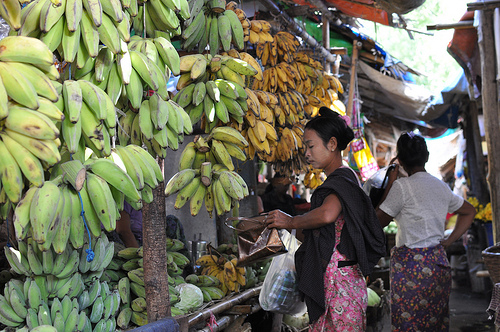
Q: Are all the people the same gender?
A: Yes, all the people are female.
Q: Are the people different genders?
A: No, all the people are female.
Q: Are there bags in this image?
A: Yes, there is a bag.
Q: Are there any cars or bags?
A: Yes, there is a bag.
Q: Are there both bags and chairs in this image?
A: No, there is a bag but no chairs.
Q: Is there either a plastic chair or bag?
A: Yes, there is a plastic bag.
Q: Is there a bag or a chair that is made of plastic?
A: Yes, the bag is made of plastic.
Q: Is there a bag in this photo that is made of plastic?
A: Yes, there is a bag that is made of plastic.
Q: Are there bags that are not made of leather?
A: Yes, there is a bag that is made of plastic.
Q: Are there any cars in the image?
A: No, there are no cars.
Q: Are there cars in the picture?
A: No, there are no cars.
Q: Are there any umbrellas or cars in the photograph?
A: No, there are no cars or umbrellas.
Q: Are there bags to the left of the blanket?
A: Yes, there is a bag to the left of the blanket.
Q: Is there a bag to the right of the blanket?
A: No, the bag is to the left of the blanket.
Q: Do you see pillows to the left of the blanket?
A: No, there is a bag to the left of the blanket.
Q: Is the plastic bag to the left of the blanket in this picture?
A: Yes, the bag is to the left of the blanket.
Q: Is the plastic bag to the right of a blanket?
A: No, the bag is to the left of a blanket.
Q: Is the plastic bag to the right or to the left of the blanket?
A: The bag is to the left of the blanket.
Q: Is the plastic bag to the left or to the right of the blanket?
A: The bag is to the left of the blanket.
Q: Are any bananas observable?
A: Yes, there are bananas.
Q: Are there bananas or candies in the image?
A: Yes, there are bananas.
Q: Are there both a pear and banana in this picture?
A: No, there are bananas but no pears.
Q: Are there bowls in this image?
A: No, there are no bowls.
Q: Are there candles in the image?
A: No, there are no candles.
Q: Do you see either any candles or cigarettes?
A: No, there are no candles or cigarettes.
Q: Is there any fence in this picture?
A: No, there are no fences.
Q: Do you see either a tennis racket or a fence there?
A: No, there are no fences or rackets.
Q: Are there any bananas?
A: Yes, there are bananas.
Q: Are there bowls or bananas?
A: Yes, there are bananas.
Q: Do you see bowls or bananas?
A: Yes, there are bananas.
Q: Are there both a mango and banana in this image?
A: No, there are bananas but no mangoes.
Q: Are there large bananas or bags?
A: Yes, there are large bananas.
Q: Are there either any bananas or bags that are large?
A: Yes, the bananas are large.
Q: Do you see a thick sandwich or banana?
A: Yes, there are thick bananas.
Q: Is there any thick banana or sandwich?
A: Yes, there are thick bananas.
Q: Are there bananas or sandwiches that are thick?
A: Yes, the bananas are thick.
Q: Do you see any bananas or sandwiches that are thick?
A: Yes, the bananas are thick.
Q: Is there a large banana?
A: Yes, there are large bananas.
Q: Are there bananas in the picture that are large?
A: Yes, there are bananas that are large.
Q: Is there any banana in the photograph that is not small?
A: Yes, there are large bananas.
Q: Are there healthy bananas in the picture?
A: Yes, there are healthy bananas.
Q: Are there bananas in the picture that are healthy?
A: Yes, there are bananas that are healthy.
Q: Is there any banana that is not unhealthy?
A: Yes, there are healthy bananas.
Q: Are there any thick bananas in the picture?
A: Yes, there are thick bananas.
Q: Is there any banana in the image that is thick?
A: Yes, there are bananas that are thick.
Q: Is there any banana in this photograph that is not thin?
A: Yes, there are thick bananas.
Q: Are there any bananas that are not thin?
A: Yes, there are thick bananas.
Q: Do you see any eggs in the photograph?
A: No, there are no eggs.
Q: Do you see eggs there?
A: No, there are no eggs.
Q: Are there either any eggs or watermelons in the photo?
A: No, there are no eggs or watermelons.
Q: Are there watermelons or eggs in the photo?
A: No, there are no eggs or watermelons.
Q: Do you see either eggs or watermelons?
A: No, there are no eggs or watermelons.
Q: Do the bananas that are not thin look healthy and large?
A: Yes, the bananas are healthy and large.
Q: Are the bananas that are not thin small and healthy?
A: No, the bananas are healthy but large.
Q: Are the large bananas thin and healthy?
A: No, the bananas are healthy but thick.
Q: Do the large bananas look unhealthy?
A: No, the bananas are healthy.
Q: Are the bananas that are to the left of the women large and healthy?
A: Yes, the bananas are large and healthy.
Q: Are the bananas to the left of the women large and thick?
A: Yes, the bananas are large and thick.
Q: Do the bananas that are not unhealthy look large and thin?
A: No, the bananas are large but thick.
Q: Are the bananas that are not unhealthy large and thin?
A: No, the bananas are large but thick.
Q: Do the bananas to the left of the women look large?
A: Yes, the bananas are large.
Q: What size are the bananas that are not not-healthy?
A: The bananas are large.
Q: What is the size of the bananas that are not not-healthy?
A: The bananas are large.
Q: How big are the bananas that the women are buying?
A: The bananas are large.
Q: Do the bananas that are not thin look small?
A: No, the bananas are large.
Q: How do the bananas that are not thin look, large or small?
A: The bananas are large.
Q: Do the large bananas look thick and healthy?
A: Yes, the bananas are thick and healthy.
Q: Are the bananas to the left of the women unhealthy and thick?
A: No, the bananas are thick but healthy.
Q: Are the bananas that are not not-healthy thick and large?
A: Yes, the bananas are thick and large.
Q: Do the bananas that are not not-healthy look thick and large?
A: Yes, the bananas are thick and large.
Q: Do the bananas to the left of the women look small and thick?
A: No, the bananas are thick but large.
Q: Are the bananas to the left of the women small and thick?
A: No, the bananas are thick but large.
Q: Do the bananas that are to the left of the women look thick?
A: Yes, the bananas are thick.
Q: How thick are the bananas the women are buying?
A: The bananas are thick.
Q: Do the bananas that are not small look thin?
A: No, the bananas are thick.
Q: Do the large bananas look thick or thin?
A: The bananas are thick.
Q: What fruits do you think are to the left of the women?
A: The fruits are bananas.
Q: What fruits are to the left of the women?
A: The fruits are bananas.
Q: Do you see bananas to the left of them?
A: Yes, there are bananas to the left of the women.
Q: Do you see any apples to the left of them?
A: No, there are bananas to the left of the women.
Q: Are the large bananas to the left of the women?
A: Yes, the bananas are to the left of the women.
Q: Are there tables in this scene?
A: Yes, there is a table.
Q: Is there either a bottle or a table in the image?
A: Yes, there is a table.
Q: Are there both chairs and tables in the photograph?
A: No, there is a table but no chairs.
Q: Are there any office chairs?
A: No, there are no office chairs.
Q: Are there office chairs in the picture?
A: No, there are no office chairs.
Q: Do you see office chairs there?
A: No, there are no office chairs.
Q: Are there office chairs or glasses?
A: No, there are no office chairs or glasses.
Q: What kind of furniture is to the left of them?
A: The piece of furniture is a table.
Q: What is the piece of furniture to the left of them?
A: The piece of furniture is a table.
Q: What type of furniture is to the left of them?
A: The piece of furniture is a table.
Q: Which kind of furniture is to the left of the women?
A: The piece of furniture is a table.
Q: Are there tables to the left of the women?
A: Yes, there is a table to the left of the women.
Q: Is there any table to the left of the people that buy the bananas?
A: Yes, there is a table to the left of the women.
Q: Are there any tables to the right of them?
A: No, the table is to the left of the women.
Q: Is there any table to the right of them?
A: No, the table is to the left of the women.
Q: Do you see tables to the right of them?
A: No, the table is to the left of the women.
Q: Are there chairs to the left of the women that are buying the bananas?
A: No, there is a table to the left of the women.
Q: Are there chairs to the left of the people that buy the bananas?
A: No, there is a table to the left of the women.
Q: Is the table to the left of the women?
A: Yes, the table is to the left of the women.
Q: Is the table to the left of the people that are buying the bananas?
A: Yes, the table is to the left of the women.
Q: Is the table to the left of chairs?
A: No, the table is to the left of the women.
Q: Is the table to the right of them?
A: No, the table is to the left of the women.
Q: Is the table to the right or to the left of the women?
A: The table is to the left of the women.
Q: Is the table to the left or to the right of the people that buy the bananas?
A: The table is to the left of the women.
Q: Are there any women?
A: Yes, there are women.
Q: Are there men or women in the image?
A: Yes, there are women.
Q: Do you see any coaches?
A: No, there are no coaches.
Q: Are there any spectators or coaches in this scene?
A: No, there are no coaches or spectators.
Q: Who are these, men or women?
A: These are women.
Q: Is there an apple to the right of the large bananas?
A: No, there are women to the right of the bananas.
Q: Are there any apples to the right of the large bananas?
A: No, there are women to the right of the bananas.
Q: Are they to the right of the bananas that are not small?
A: Yes, the women are to the right of the bananas.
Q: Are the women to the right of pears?
A: No, the women are to the right of the bananas.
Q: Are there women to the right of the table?
A: Yes, there are women to the right of the table.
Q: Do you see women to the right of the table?
A: Yes, there are women to the right of the table.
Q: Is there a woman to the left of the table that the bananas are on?
A: No, the women are to the right of the table.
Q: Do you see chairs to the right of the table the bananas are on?
A: No, there are women to the right of the table.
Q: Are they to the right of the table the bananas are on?
A: Yes, the women are to the right of the table.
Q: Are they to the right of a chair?
A: No, the women are to the right of the table.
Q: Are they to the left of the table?
A: No, the women are to the right of the table.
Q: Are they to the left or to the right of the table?
A: The women are to the right of the table.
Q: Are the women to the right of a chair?
A: No, the women are to the right of the bag.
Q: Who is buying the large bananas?
A: The women are buying the bananas.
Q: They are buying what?
A: The women are buying the bananas.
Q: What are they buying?
A: The women are buying the bananas.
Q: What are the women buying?
A: The women are buying the bananas.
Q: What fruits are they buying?
A: The women are buying the bananas.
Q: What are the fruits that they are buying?
A: The fruits are bananas.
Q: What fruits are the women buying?
A: The women are buying the bananas.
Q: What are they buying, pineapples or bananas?
A: The women are buying bananas.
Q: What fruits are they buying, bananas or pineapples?
A: The women are buying bananas.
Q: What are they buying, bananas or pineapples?
A: The women are buying bananas.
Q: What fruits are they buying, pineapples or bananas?
A: The women are buying bananas.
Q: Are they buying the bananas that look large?
A: Yes, the women are buying the bananas.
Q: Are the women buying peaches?
A: No, the women are buying the bananas.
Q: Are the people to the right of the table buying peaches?
A: No, the women are buying the bananas.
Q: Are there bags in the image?
A: Yes, there is a bag.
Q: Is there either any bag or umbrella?
A: Yes, there is a bag.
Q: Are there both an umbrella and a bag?
A: No, there is a bag but no umbrellas.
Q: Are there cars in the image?
A: No, there are no cars.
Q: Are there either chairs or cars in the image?
A: No, there are no cars or chairs.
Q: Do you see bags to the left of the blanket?
A: Yes, there is a bag to the left of the blanket.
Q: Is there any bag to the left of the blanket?
A: Yes, there is a bag to the left of the blanket.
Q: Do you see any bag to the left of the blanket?
A: Yes, there is a bag to the left of the blanket.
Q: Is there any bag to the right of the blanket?
A: No, the bag is to the left of the blanket.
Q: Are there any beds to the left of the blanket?
A: No, there is a bag to the left of the blanket.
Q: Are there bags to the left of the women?
A: Yes, there is a bag to the left of the women.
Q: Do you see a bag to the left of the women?
A: Yes, there is a bag to the left of the women.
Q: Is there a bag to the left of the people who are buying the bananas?
A: Yes, there is a bag to the left of the women.